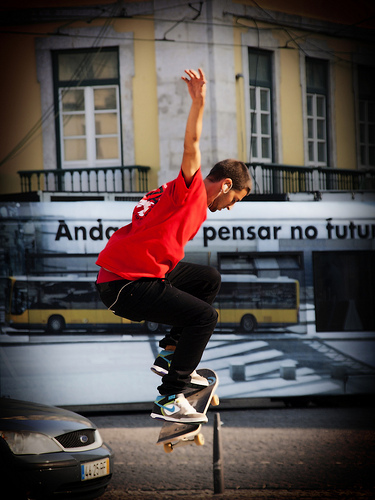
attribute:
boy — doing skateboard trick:
[89, 66, 255, 455]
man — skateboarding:
[92, 63, 264, 451]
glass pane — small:
[61, 113, 86, 134]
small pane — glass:
[95, 111, 119, 136]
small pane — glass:
[93, 135, 121, 158]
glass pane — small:
[61, 90, 85, 112]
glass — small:
[96, 135, 120, 161]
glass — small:
[248, 87, 256, 110]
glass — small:
[260, 87, 270, 112]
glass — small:
[258, 111, 271, 136]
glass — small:
[261, 134, 271, 159]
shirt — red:
[93, 166, 208, 279]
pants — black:
[94, 261, 222, 397]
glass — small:
[89, 86, 119, 111]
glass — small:
[316, 95, 326, 118]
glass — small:
[317, 117, 325, 139]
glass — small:
[317, 140, 327, 163]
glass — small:
[306, 116, 315, 139]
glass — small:
[305, 95, 315, 116]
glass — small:
[261, 112, 271, 137]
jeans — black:
[97, 259, 222, 394]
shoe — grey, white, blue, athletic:
[134, 362, 203, 416]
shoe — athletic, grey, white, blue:
[145, 334, 209, 389]